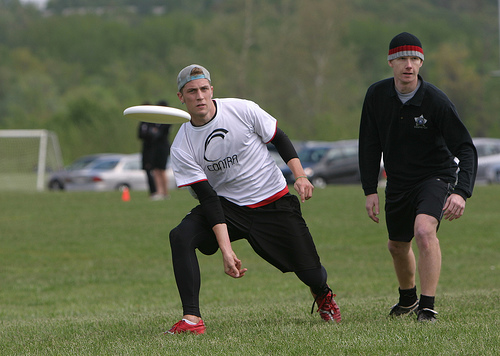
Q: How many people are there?
A: Two.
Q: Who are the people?
A: Men.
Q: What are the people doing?
A: Playing Frisbee.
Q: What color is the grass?
A: Green.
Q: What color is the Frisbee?
A: White.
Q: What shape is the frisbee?
A: Round.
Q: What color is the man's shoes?
A: Red.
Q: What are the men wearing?
A: Hats.